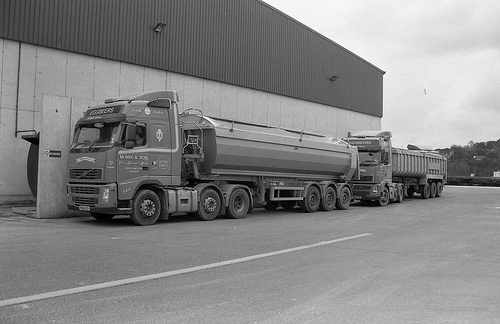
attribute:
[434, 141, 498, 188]
mountains — rocky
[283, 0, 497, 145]
clouds — white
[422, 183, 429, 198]
wheel — rubber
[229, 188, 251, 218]
wheel — rubber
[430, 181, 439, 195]
wheel — rubber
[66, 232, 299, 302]
line — white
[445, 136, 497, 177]
mountains — rocky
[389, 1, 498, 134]
clouds — white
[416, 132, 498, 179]
mountains — rocky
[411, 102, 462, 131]
clouds — white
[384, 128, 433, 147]
clouds — white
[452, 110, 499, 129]
clouds — white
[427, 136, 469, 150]
clouds — white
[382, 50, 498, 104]
clouds — white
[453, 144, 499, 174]
mountains — rocky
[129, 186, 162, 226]
wheel — rubber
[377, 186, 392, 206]
wheel — rubber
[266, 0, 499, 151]
clouds — white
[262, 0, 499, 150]
cloud — thick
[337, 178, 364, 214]
wheel — rubber